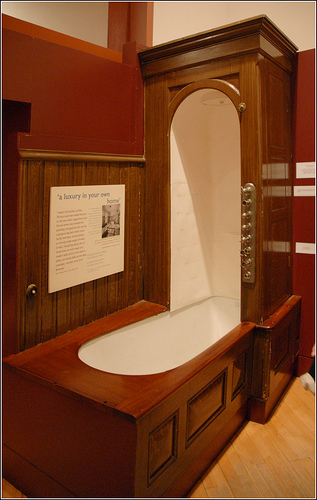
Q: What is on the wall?
A: A sign with words.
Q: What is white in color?
A: The tub.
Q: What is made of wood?
A: The tub base.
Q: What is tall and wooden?
A: The shower.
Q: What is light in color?
A: The wood floor.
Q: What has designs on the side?
A: The wooden tub.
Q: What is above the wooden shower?
A: A white wall.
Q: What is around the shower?
A: A large wooden frame.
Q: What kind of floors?
A: Wood.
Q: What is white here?
A: The tub.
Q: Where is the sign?
A: On the wall.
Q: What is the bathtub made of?
A: Tile and wood.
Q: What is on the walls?
A: Red and white paint and paneling.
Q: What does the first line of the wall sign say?
A: A luxury in your own home.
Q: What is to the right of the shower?
A: A set of 8 fixtures.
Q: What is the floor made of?
A: Wood.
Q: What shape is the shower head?
A: Circle.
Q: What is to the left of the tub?
A: A sign and buzzer.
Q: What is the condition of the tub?
A: Slightly worn.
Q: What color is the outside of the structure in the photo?
A: Brown.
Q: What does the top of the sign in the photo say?
A: "a luxury in your own home".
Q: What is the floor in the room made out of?
A: Wood.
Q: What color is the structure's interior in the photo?
A: White.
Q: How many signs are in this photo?
A: One.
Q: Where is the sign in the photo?
A: On the wall.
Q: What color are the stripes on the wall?
A: White.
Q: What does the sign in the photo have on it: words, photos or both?
A: Both.